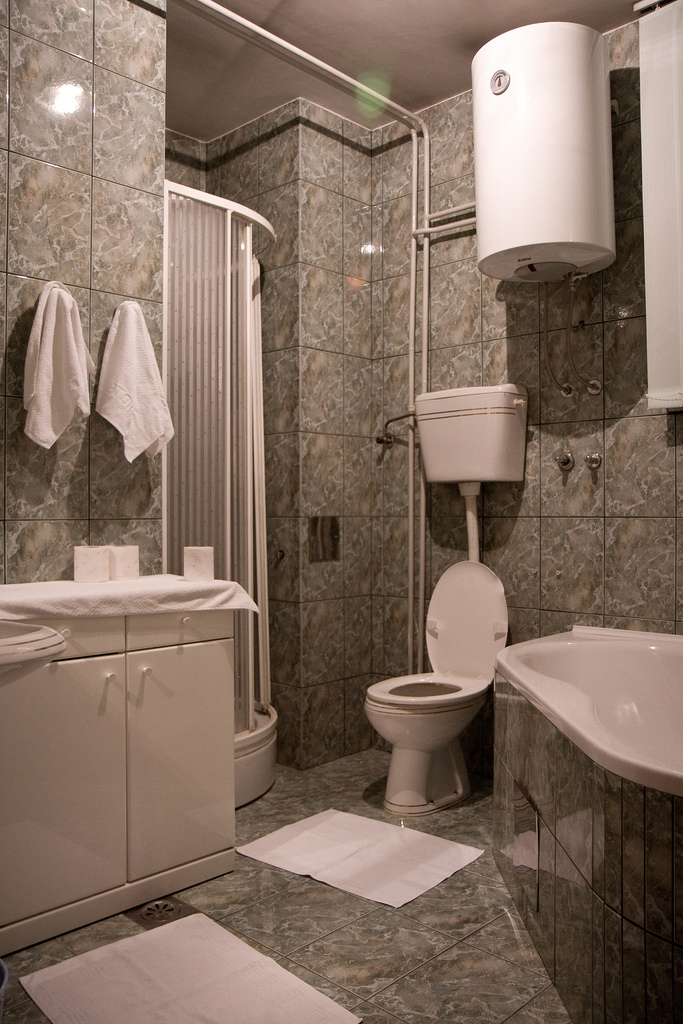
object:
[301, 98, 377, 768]
wall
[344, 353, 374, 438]
tile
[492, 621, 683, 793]
tub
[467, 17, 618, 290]
tank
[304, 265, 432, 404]
marble tile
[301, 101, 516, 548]
bathroom wall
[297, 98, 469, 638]
marble tile